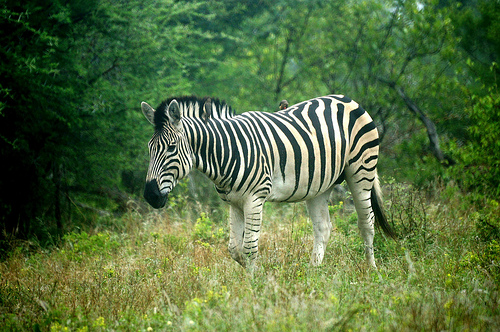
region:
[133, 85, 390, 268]
Black and white zebra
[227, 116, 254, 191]
Black stripe on zebra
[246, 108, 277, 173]
Black stripe on zebra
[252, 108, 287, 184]
Black stripe on zebra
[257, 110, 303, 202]
Black stripe on zebra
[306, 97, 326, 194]
Black stripe on zebra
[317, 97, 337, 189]
Black stripe on zebra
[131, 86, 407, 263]
a zebra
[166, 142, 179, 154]
left eye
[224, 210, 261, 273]
the zebras front legs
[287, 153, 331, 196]
the zebras belly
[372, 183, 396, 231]
the zebras tail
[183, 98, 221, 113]
the hair is black and white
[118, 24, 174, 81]
green leaves on the tree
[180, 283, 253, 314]
the grass is tall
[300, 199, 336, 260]
back leg of the zebra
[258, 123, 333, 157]
the pattern on the zebra is black and white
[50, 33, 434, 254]
this is a zebra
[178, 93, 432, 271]
the zebra is white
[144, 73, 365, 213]
the zebra is black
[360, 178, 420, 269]
the tail is black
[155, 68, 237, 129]
the zebra has a mane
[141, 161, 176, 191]
the nose is black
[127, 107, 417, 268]
the zebra is standing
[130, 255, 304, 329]
the grass is brown and green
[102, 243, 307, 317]
the grass is dry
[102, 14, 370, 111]
the trees are very lush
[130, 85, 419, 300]
This is a zebra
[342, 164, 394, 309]
Leg of a zebra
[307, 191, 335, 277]
Leg of a zebra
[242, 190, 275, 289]
Leg of a zebra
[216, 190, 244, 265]
Leg of a zebra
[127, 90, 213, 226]
Head of a zebra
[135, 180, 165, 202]
Nose of a zebra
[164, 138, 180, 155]
Eye of a zebra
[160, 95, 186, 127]
Ear of a zebra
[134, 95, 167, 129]
Ear of a zebra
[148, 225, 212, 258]
the flowers are yellow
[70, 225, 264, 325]
flowers in the grass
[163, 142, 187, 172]
eyes on the head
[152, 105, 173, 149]
mane on the head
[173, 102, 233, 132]
the mane is striped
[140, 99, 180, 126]
the ears are pointed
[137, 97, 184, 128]
mane between the ears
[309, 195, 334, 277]
the inner leg is white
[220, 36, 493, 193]
trees behind the zebra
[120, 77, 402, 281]
zebra's fur is stripes